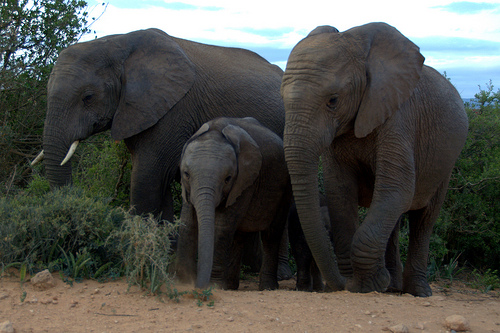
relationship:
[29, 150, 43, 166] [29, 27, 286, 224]
tusk on poppa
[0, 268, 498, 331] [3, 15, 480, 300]
brown dirt in front of elephants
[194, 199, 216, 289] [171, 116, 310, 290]
trunk on baby elephant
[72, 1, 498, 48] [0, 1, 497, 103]
clouds in sky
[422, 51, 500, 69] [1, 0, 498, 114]
clouds in sky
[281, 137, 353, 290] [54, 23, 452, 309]
trunks on elephants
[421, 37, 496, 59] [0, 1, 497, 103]
patches in sky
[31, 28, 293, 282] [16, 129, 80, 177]
elephants has tusks